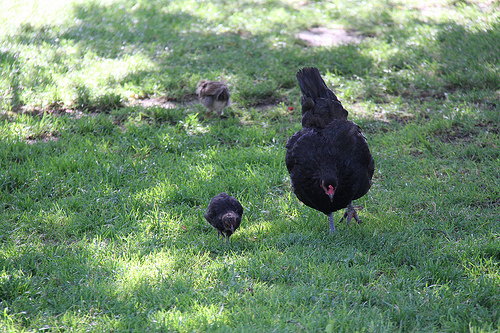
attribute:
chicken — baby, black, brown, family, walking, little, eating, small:
[200, 190, 245, 240]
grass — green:
[113, 149, 157, 200]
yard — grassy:
[12, 11, 159, 309]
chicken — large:
[301, 84, 369, 239]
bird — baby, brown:
[199, 79, 229, 114]